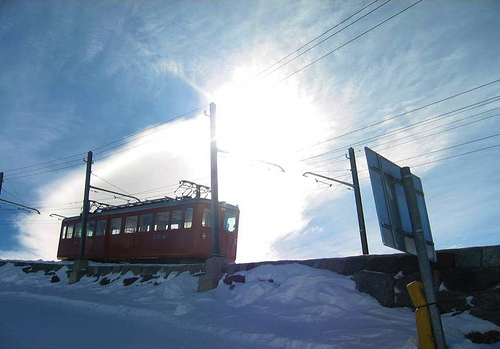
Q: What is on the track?
A: A trolley car.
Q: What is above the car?
A: Wires.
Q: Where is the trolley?
A: On the tracks.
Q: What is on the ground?
A: Snow.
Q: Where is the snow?
A: On the ground.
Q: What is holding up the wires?
A: Poles.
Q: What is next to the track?
A: A sign.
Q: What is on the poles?
A: Wires.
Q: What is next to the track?
A: Snow.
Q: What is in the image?
A: Tramcar line.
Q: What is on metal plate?
A: White sign.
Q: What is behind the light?
A: Tram.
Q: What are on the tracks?
A: Train.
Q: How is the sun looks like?
A: Breaking through clouds.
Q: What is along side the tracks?
A: Sign.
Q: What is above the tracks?
A: Phone wires.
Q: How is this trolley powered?
A: Electric power.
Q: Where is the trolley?
A: On tracks.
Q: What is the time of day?
A: Sunset.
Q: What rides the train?
A: Passengers.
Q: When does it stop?
A: At a destination.